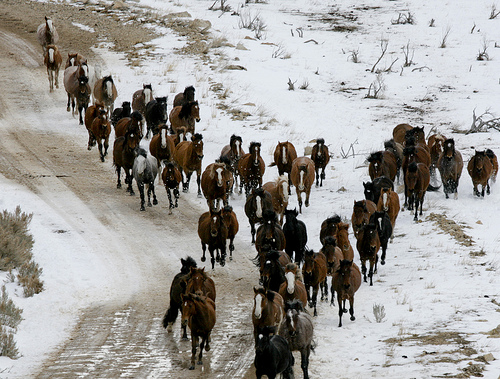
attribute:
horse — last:
[35, 14, 60, 51]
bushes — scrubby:
[0, 202, 48, 360]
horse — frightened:
[331, 257, 360, 326]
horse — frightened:
[132, 145, 159, 211]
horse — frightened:
[289, 155, 314, 213]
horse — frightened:
[310, 137, 330, 187]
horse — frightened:
[267, 140, 298, 196]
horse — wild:
[176, 291, 223, 371]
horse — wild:
[462, 147, 494, 197]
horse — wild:
[372, 183, 402, 236]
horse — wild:
[286, 153, 317, 213]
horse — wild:
[196, 156, 238, 211]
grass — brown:
[1, 212, 38, 288]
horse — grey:
[161, 149, 194, 219]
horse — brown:
[435, 137, 466, 189]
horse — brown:
[332, 252, 369, 312]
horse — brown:
[374, 186, 408, 236]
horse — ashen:
[128, 145, 162, 212]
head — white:
[251, 285, 262, 325]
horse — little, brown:
[159, 158, 188, 214]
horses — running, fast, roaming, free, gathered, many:
[29, 18, 494, 376]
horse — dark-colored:
[252, 322, 296, 377]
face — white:
[251, 325, 272, 356]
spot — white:
[256, 330, 263, 340]